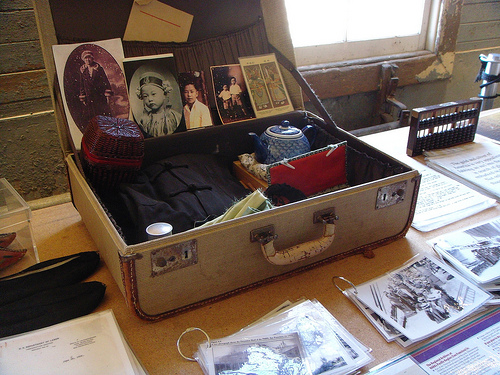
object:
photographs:
[47, 33, 300, 146]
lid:
[27, 0, 312, 155]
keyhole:
[181, 242, 193, 262]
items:
[6, 89, 484, 364]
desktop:
[8, 110, 496, 373]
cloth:
[109, 149, 249, 242]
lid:
[267, 140, 350, 190]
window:
[286, 1, 446, 61]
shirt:
[133, 149, 222, 216]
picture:
[68, 37, 125, 147]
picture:
[138, 60, 170, 145]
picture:
[174, 68, 215, 132]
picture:
[213, 57, 244, 124]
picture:
[248, 49, 289, 117]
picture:
[342, 214, 499, 348]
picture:
[195, 299, 366, 374]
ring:
[174, 325, 211, 361]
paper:
[391, 136, 500, 233]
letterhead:
[13, 318, 150, 373]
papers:
[3, 301, 141, 372]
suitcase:
[31, 0, 422, 322]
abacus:
[406, 96, 483, 158]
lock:
[374, 178, 419, 215]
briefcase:
[29, 0, 420, 323]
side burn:
[246, 115, 316, 167]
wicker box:
[81, 109, 160, 181]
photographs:
[171, 225, 500, 374]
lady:
[74, 51, 114, 116]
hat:
[79, 49, 92, 58]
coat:
[77, 62, 113, 119]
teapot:
[247, 118, 330, 166]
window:
[257, 0, 461, 94]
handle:
[251, 208, 341, 266]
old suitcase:
[27, 0, 422, 320]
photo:
[211, 61, 256, 122]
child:
[216, 81, 231, 112]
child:
[228, 76, 249, 114]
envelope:
[120, 3, 194, 44]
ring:
[324, 265, 360, 297]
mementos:
[45, 7, 373, 237]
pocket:
[58, 26, 268, 113]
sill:
[305, 47, 463, 99]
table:
[2, 172, 462, 372]